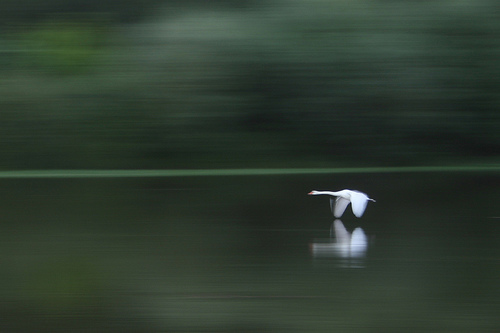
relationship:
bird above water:
[304, 179, 384, 235] [0, 2, 499, 333]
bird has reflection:
[304, 179, 384, 235] [308, 218, 377, 262]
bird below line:
[304, 179, 384, 235] [0, 161, 499, 181]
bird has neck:
[304, 179, 384, 235] [317, 186, 338, 199]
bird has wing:
[304, 179, 384, 235] [348, 189, 374, 219]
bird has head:
[304, 179, 384, 235] [306, 186, 317, 198]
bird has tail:
[304, 179, 384, 235] [366, 193, 378, 207]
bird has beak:
[304, 179, 384, 235] [305, 188, 312, 199]